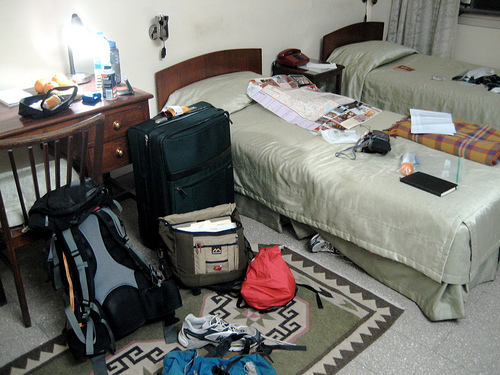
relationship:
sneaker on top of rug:
[179, 314, 261, 350] [1, 243, 405, 375]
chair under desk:
[1, 111, 107, 329] [0, 74, 153, 306]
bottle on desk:
[90, 51, 105, 89] [0, 74, 153, 306]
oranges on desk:
[34, 77, 73, 92] [0, 74, 153, 306]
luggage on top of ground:
[129, 101, 234, 251] [1, 188, 498, 374]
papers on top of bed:
[408, 107, 457, 138] [155, 47, 499, 325]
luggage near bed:
[129, 101, 234, 251] [155, 47, 499, 325]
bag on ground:
[241, 246, 299, 311] [1, 188, 498, 374]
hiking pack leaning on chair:
[24, 180, 182, 361] [1, 111, 107, 329]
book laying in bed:
[402, 170, 458, 197] [155, 47, 499, 325]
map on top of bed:
[243, 75, 380, 134] [155, 47, 499, 325]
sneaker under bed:
[309, 233, 341, 255] [155, 47, 499, 325]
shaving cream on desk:
[103, 66, 119, 100] [0, 74, 153, 306]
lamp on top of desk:
[67, 13, 90, 84] [0, 74, 153, 306]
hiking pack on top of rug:
[24, 180, 182, 361] [1, 243, 405, 375]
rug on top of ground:
[1, 243, 405, 375] [1, 188, 498, 374]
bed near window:
[322, 19, 499, 130] [458, 0, 499, 28]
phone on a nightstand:
[277, 48, 312, 67] [272, 59, 345, 95]